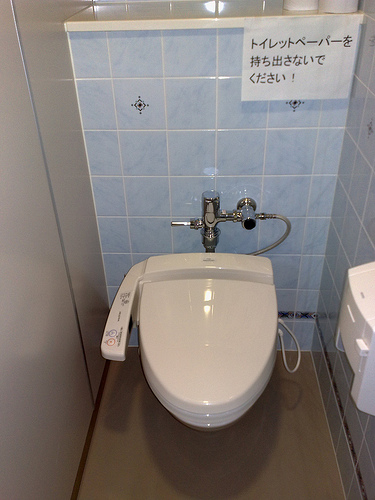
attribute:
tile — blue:
[216, 125, 264, 176]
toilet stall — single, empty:
[3, 17, 369, 498]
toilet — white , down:
[97, 192, 303, 430]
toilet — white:
[109, 251, 287, 425]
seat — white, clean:
[138, 275, 281, 391]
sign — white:
[241, 18, 359, 103]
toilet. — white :
[109, 209, 305, 425]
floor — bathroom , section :
[139, 424, 326, 484]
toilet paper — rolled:
[319, 2, 360, 13]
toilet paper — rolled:
[282, 1, 316, 13]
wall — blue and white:
[66, 23, 374, 498]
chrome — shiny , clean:
[166, 182, 299, 257]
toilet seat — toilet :
[145, 258, 276, 431]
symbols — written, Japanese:
[239, 14, 361, 111]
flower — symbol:
[111, 77, 166, 129]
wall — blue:
[65, 23, 352, 366]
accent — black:
[283, 94, 301, 112]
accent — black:
[127, 93, 150, 117]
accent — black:
[277, 299, 314, 331]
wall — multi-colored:
[71, 29, 223, 184]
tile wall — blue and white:
[68, 29, 334, 369]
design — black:
[127, 93, 150, 118]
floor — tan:
[111, 345, 344, 497]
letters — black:
[247, 32, 356, 85]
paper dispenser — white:
[333, 260, 373, 419]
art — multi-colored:
[129, 94, 149, 113]